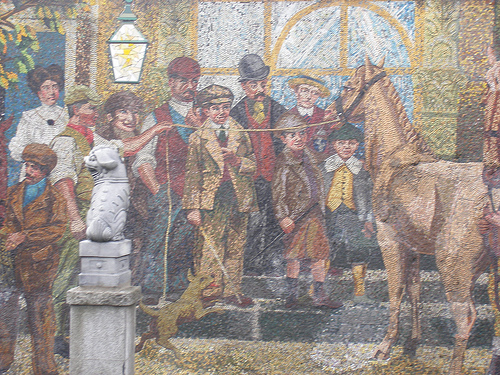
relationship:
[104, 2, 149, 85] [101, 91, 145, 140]
lantern above man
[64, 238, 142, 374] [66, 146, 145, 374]
base of statue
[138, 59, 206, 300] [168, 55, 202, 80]
man wearing hat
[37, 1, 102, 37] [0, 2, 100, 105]
leaves on tree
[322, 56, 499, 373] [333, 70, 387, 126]
horse wearing bridle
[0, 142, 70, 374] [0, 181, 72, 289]
man wearing jacket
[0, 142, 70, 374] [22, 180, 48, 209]
man wearing scarf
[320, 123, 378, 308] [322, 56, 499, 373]
boy looking at horse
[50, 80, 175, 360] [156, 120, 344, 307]
man holding rope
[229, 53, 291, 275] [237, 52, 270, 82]
man wearing hat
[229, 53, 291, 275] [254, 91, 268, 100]
man has mustache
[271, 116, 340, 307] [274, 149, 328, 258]
boy wearing suit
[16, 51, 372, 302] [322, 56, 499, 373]
people looking at horse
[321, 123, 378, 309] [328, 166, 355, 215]
boy wearing vest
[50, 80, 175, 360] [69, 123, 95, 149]
man wearing scarf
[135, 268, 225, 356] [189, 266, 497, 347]
dog by steps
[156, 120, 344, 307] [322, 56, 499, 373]
rope attached to horse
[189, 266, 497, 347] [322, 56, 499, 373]
steps next to horse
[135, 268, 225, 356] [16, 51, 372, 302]
dog in front of people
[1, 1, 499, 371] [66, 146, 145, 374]
painting behind statue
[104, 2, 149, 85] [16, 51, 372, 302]
lantern above people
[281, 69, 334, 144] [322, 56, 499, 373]
man standing near horse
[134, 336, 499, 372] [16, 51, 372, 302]
ground in front of people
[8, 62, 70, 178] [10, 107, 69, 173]
woman wearing white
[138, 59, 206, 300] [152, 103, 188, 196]
man wearing vest